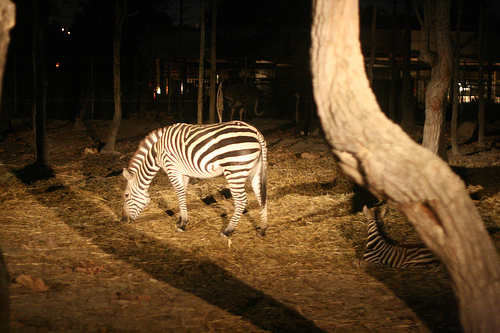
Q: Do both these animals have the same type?
A: Yes, all the animals are zebras.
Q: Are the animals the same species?
A: Yes, all the animals are zebras.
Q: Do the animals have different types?
A: No, all the animals are zebras.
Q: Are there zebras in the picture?
A: Yes, there is a zebra.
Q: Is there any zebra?
A: Yes, there is a zebra.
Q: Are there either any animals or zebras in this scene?
A: Yes, there is a zebra.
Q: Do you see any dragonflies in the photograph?
A: No, there are no dragonflies.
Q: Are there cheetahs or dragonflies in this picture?
A: No, there are no dragonflies or cheetahs.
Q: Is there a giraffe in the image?
A: No, there are no giraffes.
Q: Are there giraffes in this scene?
A: No, there are no giraffes.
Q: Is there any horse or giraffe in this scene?
A: No, there are no giraffes or horses.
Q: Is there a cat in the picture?
A: No, there are no cats.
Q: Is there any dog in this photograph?
A: No, there are no dogs.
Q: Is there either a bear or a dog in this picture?
A: No, there are no dogs or bears.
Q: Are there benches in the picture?
A: No, there are no benches.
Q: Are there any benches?
A: No, there are no benches.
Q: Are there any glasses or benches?
A: No, there are no benches or glasses.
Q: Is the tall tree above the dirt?
A: Yes, the tree is above the dirt.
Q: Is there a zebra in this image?
A: Yes, there is a zebra.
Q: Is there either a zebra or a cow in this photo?
A: Yes, there is a zebra.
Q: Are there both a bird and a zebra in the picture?
A: No, there is a zebra but no birds.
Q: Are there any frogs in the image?
A: No, there are no frogs.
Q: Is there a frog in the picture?
A: No, there are no frogs.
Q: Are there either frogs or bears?
A: No, there are no frogs or bears.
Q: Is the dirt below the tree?
A: Yes, the dirt is below the tree.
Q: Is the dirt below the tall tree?
A: Yes, the dirt is below the tree.